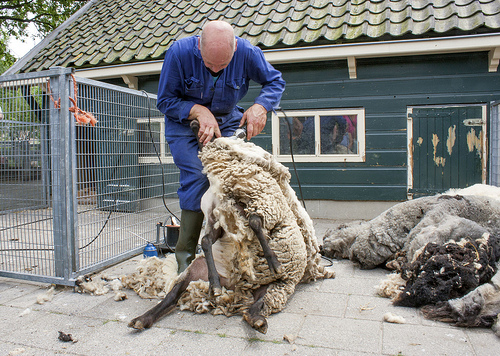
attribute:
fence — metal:
[73, 79, 160, 274]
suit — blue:
[155, 36, 285, 208]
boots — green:
[163, 203, 208, 293]